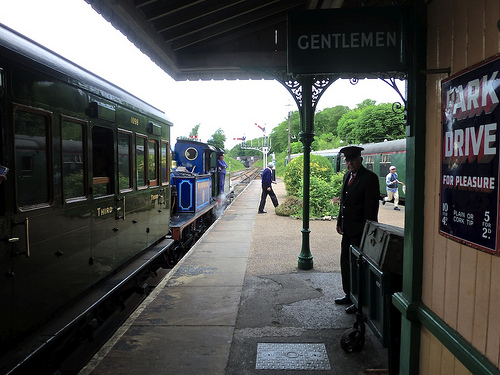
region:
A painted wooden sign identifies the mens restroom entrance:
[281, 13, 411, 80]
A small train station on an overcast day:
[0, 14, 496, 373]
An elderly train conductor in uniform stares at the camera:
[331, 142, 381, 313]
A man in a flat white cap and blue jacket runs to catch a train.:
[380, 162, 407, 212]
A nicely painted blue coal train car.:
[171, 134, 219, 233]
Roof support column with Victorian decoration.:
[272, 72, 341, 269]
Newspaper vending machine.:
[342, 220, 402, 366]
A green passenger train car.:
[1, 37, 176, 362]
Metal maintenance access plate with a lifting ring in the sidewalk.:
[253, 340, 333, 372]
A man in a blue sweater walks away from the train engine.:
[255, 160, 284, 216]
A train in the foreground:
[1, 15, 234, 373]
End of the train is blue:
[165, 125, 245, 259]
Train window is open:
[77, 115, 130, 210]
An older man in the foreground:
[322, 132, 377, 327]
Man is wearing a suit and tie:
[326, 166, 385, 325]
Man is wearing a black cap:
[331, 135, 371, 165]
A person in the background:
[251, 153, 288, 220]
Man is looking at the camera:
[331, 133, 369, 176]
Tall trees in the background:
[188, 92, 408, 161]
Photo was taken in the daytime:
[2, 6, 495, 374]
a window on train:
[21, 121, 41, 180]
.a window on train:
[87, 124, 119, 191]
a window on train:
[114, 135, 143, 187]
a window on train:
[137, 135, 159, 202]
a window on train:
[137, 134, 152, 182]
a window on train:
[144, 137, 156, 175]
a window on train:
[159, 140, 176, 192]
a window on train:
[181, 146, 196, 160]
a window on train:
[203, 149, 218, 175]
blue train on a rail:
[166, 135, 228, 241]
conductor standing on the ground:
[335, 145, 380, 317]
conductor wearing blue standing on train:
[215, 152, 227, 195]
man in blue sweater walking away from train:
[259, 161, 280, 213]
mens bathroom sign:
[289, 6, 407, 76]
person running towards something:
[380, 165, 405, 212]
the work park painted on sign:
[442, 71, 498, 123]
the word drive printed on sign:
[440, 124, 496, 164]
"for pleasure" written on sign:
[440, 174, 497, 191]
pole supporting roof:
[295, 67, 315, 276]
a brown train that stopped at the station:
[7, 28, 175, 349]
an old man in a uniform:
[317, 146, 384, 283]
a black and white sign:
[442, 65, 497, 259]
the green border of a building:
[394, 202, 422, 249]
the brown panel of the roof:
[100, 13, 237, 77]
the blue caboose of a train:
[157, 129, 221, 210]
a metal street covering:
[245, 343, 345, 373]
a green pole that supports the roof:
[280, 79, 322, 274]